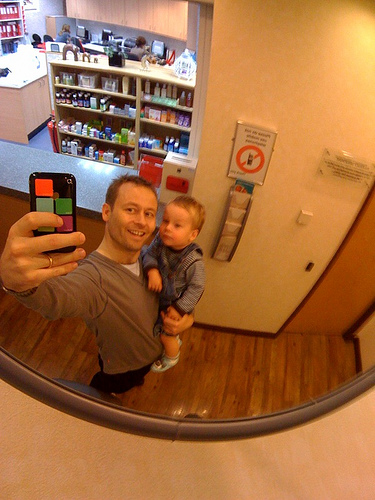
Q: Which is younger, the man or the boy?
A: The boy is younger than the man.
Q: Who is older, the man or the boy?
A: The man is older than the boy.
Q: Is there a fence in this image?
A: No, there are no fences.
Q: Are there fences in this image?
A: No, there are no fences.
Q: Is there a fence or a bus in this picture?
A: No, there are no fences or buses.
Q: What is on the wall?
A: The sign is on the wall.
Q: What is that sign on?
A: The sign is on the wall.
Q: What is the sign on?
A: The sign is on the wall.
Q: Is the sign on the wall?
A: Yes, the sign is on the wall.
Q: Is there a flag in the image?
A: No, there are no flags.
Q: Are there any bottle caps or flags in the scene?
A: No, there are no flags or bottle caps.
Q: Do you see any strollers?
A: No, there are no strollers.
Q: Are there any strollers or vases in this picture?
A: No, there are no strollers or vases.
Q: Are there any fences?
A: No, there are no fences.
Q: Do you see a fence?
A: No, there are no fences.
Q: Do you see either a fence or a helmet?
A: No, there are no fences or helmets.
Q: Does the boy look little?
A: Yes, the boy is little.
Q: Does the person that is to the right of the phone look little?
A: Yes, the boy is little.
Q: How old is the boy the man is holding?
A: The boy is little.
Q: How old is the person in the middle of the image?
A: The boy is little.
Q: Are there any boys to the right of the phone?
A: Yes, there is a boy to the right of the phone.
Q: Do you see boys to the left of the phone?
A: No, the boy is to the right of the phone.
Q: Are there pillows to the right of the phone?
A: No, there is a boy to the right of the phone.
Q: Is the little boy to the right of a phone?
A: Yes, the boy is to the right of a phone.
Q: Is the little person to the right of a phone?
A: Yes, the boy is to the right of a phone.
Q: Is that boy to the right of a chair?
A: No, the boy is to the right of a phone.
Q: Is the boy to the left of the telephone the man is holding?
A: No, the boy is to the right of the phone.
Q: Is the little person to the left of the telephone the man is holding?
A: No, the boy is to the right of the phone.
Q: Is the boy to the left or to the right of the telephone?
A: The boy is to the right of the telephone.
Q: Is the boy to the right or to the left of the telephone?
A: The boy is to the right of the telephone.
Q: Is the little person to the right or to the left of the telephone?
A: The boy is to the right of the telephone.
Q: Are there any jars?
A: No, there are no jars.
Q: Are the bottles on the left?
A: Yes, the bottles are on the left of the image.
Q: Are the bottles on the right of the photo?
A: No, the bottles are on the left of the image.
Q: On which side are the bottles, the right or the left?
A: The bottles are on the left of the image.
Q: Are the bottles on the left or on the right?
A: The bottles are on the left of the image.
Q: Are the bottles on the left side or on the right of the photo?
A: The bottles are on the left of the image.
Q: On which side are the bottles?
A: The bottles are on the left of the image.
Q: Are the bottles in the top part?
A: Yes, the bottles are in the top of the image.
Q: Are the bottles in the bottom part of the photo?
A: No, the bottles are in the top of the image.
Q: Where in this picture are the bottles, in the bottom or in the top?
A: The bottles are in the top of the image.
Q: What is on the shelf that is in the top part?
A: The bottles are on the shelf.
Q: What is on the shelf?
A: The bottles are on the shelf.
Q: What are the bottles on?
A: The bottles are on the shelf.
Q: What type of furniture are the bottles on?
A: The bottles are on the shelf.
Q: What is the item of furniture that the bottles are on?
A: The piece of furniture is a shelf.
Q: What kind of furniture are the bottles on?
A: The bottles are on the shelf.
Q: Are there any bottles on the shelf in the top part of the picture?
A: Yes, there are bottles on the shelf.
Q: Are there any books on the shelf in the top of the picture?
A: No, there are bottles on the shelf.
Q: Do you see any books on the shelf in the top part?
A: No, there are bottles on the shelf.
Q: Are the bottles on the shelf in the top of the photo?
A: Yes, the bottles are on the shelf.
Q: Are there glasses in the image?
A: No, there are no glasses.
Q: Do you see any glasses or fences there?
A: No, there are no glasses or fences.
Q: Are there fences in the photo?
A: No, there are no fences.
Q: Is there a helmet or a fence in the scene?
A: No, there are no fences or helmets.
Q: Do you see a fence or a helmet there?
A: No, there are no fences or helmets.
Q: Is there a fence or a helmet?
A: No, there are no fences or helmets.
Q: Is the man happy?
A: Yes, the man is happy.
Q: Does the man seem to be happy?
A: Yes, the man is happy.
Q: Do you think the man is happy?
A: Yes, the man is happy.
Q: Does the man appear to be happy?
A: Yes, the man is happy.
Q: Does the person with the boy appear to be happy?
A: Yes, the man is happy.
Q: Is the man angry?
A: No, the man is happy.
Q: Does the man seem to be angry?
A: No, the man is happy.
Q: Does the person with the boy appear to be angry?
A: No, the man is happy.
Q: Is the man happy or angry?
A: The man is happy.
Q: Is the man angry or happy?
A: The man is happy.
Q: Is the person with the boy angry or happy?
A: The man is happy.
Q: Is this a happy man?
A: Yes, this is a happy man.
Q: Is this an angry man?
A: No, this is a happy man.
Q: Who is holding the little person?
A: The man is holding the boy.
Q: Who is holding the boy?
A: The man is holding the boy.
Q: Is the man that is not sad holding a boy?
A: Yes, the man is holding a boy.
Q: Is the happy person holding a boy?
A: Yes, the man is holding a boy.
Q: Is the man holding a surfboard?
A: No, the man is holding a boy.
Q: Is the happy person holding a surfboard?
A: No, the man is holding a boy.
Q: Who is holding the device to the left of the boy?
A: The man is holding the phone.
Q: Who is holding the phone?
A: The man is holding the phone.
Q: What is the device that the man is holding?
A: The device is a phone.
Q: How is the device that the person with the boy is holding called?
A: The device is a phone.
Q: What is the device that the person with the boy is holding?
A: The device is a phone.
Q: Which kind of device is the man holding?
A: The man is holding the telephone.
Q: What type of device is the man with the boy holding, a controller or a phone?
A: The man is holding a phone.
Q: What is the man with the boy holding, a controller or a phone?
A: The man is holding a phone.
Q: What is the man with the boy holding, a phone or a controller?
A: The man is holding a phone.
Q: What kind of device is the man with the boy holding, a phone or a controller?
A: The man is holding a phone.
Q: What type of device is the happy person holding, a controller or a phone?
A: The man is holding a phone.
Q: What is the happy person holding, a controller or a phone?
A: The man is holding a phone.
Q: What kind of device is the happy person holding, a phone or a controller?
A: The man is holding a phone.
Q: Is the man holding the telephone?
A: Yes, the man is holding the telephone.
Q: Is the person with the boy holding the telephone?
A: Yes, the man is holding the telephone.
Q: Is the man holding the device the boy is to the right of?
A: Yes, the man is holding the telephone.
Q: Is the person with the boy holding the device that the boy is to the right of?
A: Yes, the man is holding the telephone.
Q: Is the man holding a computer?
A: No, the man is holding the telephone.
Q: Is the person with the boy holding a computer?
A: No, the man is holding the telephone.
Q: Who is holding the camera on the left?
A: The man is holding the camera.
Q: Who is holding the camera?
A: The man is holding the camera.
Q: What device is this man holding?
A: The man is holding the camera.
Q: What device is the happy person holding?
A: The man is holding the camera.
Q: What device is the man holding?
A: The man is holding the camera.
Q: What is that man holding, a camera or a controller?
A: The man is holding a camera.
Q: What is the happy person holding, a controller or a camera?
A: The man is holding a camera.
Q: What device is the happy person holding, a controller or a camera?
A: The man is holding a camera.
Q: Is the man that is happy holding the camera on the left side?
A: Yes, the man is holding the camera.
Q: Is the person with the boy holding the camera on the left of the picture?
A: Yes, the man is holding the camera.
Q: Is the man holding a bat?
A: No, the man is holding the camera.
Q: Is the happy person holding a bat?
A: No, the man is holding the camera.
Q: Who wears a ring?
A: The man wears a ring.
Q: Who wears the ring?
A: The man wears a ring.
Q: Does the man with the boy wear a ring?
A: Yes, the man wears a ring.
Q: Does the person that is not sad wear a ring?
A: Yes, the man wears a ring.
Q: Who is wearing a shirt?
A: The man is wearing a shirt.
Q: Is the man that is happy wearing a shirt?
A: Yes, the man is wearing a shirt.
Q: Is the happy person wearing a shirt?
A: Yes, the man is wearing a shirt.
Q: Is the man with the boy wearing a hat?
A: No, the man is wearing a shirt.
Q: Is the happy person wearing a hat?
A: No, the man is wearing a shirt.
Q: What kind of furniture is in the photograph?
A: The furniture is a shelf.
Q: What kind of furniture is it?
A: The piece of furniture is a shelf.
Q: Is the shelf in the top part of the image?
A: Yes, the shelf is in the top of the image.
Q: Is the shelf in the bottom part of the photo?
A: No, the shelf is in the top of the image.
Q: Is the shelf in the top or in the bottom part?
A: The shelf is in the top of the image.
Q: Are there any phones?
A: Yes, there is a phone.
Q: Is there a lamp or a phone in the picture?
A: Yes, there is a phone.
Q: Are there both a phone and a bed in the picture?
A: No, there is a phone but no beds.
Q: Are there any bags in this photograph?
A: No, there are no bags.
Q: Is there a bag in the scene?
A: No, there are no bags.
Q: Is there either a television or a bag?
A: No, there are no bags or televisions.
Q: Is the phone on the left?
A: Yes, the phone is on the left of the image.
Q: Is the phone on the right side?
A: No, the phone is on the left of the image.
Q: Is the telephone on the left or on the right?
A: The telephone is on the left of the image.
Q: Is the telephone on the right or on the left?
A: The telephone is on the left of the image.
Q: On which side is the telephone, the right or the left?
A: The telephone is on the left of the image.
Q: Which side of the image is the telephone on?
A: The telephone is on the left of the image.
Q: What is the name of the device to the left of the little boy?
A: The device is a phone.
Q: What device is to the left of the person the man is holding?
A: The device is a phone.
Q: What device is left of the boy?
A: The device is a phone.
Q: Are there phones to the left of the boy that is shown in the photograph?
A: Yes, there is a phone to the left of the boy.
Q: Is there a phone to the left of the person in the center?
A: Yes, there is a phone to the left of the boy.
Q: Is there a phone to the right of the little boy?
A: No, the phone is to the left of the boy.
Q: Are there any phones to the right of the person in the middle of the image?
A: No, the phone is to the left of the boy.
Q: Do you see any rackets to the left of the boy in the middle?
A: No, there is a phone to the left of the boy.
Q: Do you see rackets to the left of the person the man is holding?
A: No, there is a phone to the left of the boy.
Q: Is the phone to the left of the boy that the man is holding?
A: Yes, the phone is to the left of the boy.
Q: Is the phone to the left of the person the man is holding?
A: Yes, the phone is to the left of the boy.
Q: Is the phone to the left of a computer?
A: No, the phone is to the left of the boy.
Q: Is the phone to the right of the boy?
A: No, the phone is to the left of the boy.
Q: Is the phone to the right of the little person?
A: No, the phone is to the left of the boy.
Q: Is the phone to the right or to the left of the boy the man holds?
A: The phone is to the left of the boy.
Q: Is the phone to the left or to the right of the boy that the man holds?
A: The phone is to the left of the boy.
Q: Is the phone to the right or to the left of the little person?
A: The phone is to the left of the boy.